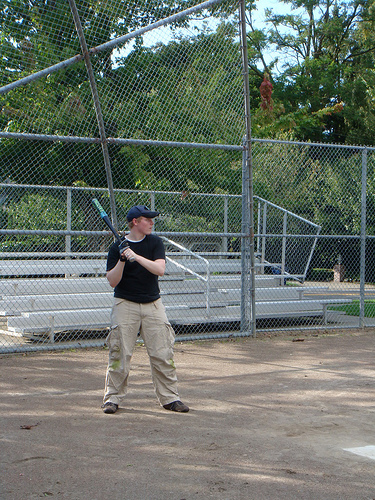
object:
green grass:
[347, 303, 358, 314]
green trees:
[256, 7, 362, 135]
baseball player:
[101, 203, 190, 417]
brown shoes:
[162, 400, 191, 413]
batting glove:
[117, 238, 129, 261]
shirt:
[106, 235, 167, 306]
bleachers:
[0, 185, 352, 336]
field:
[199, 352, 373, 467]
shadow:
[67, 427, 198, 471]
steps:
[20, 280, 88, 320]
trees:
[282, 60, 368, 130]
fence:
[7, 12, 236, 194]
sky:
[258, 4, 313, 63]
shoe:
[101, 399, 120, 414]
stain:
[108, 355, 124, 370]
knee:
[106, 338, 134, 374]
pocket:
[161, 316, 177, 348]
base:
[90, 196, 129, 250]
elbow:
[104, 270, 123, 289]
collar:
[124, 235, 147, 244]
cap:
[124, 205, 160, 220]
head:
[126, 205, 158, 237]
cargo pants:
[102, 298, 180, 407]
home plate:
[344, 445, 371, 459]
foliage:
[302, 74, 349, 127]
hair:
[127, 218, 133, 228]